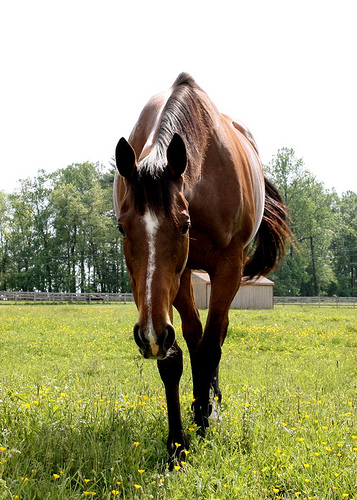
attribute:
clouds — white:
[24, 39, 122, 129]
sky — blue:
[49, 3, 326, 108]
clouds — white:
[7, 0, 353, 182]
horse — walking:
[110, 70, 304, 475]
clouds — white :
[0, 21, 354, 191]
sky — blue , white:
[2, 0, 355, 293]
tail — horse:
[241, 175, 301, 284]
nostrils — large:
[137, 320, 174, 353]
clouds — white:
[249, 20, 356, 191]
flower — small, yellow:
[132, 481, 142, 489]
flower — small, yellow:
[137, 467, 145, 475]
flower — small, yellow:
[138, 402, 146, 406]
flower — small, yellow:
[272, 486, 279, 493]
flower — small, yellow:
[23, 402, 32, 409]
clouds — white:
[32, 37, 134, 93]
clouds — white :
[262, 32, 304, 86]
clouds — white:
[275, 40, 344, 112]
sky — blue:
[2, 5, 355, 209]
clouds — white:
[300, 43, 336, 82]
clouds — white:
[22, 86, 61, 122]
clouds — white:
[98, 30, 131, 48]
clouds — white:
[212, 22, 249, 68]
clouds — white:
[305, 118, 352, 152]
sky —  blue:
[2, 22, 355, 192]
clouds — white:
[42, 33, 141, 90]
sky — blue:
[8, 51, 355, 191]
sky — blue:
[12, 42, 353, 101]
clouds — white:
[38, 44, 228, 77]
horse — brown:
[75, 49, 327, 405]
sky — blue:
[6, 37, 118, 149]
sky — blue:
[236, 29, 322, 139]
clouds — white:
[213, 36, 266, 68]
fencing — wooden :
[0, 290, 134, 302]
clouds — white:
[244, 6, 344, 132]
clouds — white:
[18, 149, 114, 243]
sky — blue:
[25, 39, 355, 188]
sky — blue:
[8, 14, 342, 187]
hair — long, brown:
[258, 173, 302, 275]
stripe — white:
[138, 210, 178, 352]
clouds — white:
[43, 13, 129, 84]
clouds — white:
[209, 66, 324, 96]